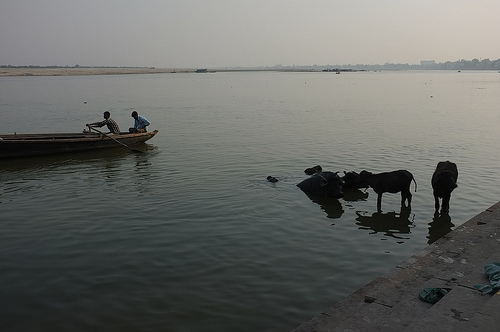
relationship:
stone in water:
[268, 174, 280, 183] [4, 1, 500, 323]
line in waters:
[3, 55, 500, 74] [5, 58, 500, 325]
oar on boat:
[89, 126, 137, 155] [1, 117, 162, 162]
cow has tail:
[354, 164, 416, 221] [415, 176, 421, 195]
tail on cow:
[415, 176, 421, 195] [354, 164, 416, 221]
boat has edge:
[1, 117, 162, 162] [2, 130, 160, 146]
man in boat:
[83, 110, 125, 139] [1, 117, 162, 162]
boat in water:
[1, 117, 162, 162] [4, 1, 500, 323]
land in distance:
[1, 66, 204, 79] [3, 0, 495, 133]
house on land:
[195, 67, 211, 71] [1, 66, 204, 79]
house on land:
[71, 62, 82, 72] [1, 66, 204, 79]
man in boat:
[128, 109, 153, 135] [1, 117, 162, 162]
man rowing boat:
[83, 110, 125, 139] [1, 117, 162, 162]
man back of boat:
[128, 109, 153, 135] [1, 117, 162, 162]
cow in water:
[354, 164, 416, 221] [4, 1, 500, 323]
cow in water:
[429, 158, 460, 218] [4, 1, 500, 323]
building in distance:
[324, 67, 356, 72] [3, 0, 495, 133]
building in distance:
[419, 59, 439, 63] [3, 0, 495, 133]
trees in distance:
[260, 55, 500, 72] [3, 0, 495, 133]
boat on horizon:
[1, 117, 162, 162] [3, 0, 495, 133]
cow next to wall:
[354, 164, 416, 221] [291, 198, 500, 330]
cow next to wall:
[429, 158, 460, 218] [291, 198, 500, 330]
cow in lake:
[354, 164, 416, 221] [5, 65, 500, 321]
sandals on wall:
[421, 280, 456, 303] [291, 198, 500, 330]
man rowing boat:
[128, 109, 153, 135] [1, 117, 162, 162]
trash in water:
[299, 161, 363, 201] [4, 1, 500, 323]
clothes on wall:
[472, 257, 500, 303] [291, 198, 500, 330]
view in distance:
[5, 40, 499, 97] [3, 0, 495, 133]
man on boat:
[83, 110, 125, 139] [1, 117, 162, 162]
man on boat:
[128, 109, 153, 135] [1, 117, 162, 162]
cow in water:
[295, 168, 346, 203] [4, 1, 500, 323]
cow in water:
[341, 166, 369, 192] [4, 1, 500, 323]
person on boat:
[128, 109, 153, 135] [1, 117, 162, 162]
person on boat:
[83, 110, 125, 139] [1, 117, 162, 162]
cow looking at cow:
[354, 164, 416, 221] [295, 168, 346, 203]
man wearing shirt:
[128, 109, 153, 135] [131, 117, 152, 131]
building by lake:
[324, 67, 356, 72] [5, 65, 500, 321]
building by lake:
[419, 59, 439, 63] [5, 65, 500, 321]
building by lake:
[195, 66, 212, 77] [5, 65, 500, 321]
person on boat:
[88, 108, 122, 138] [1, 117, 162, 162]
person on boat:
[127, 103, 156, 132] [1, 117, 162, 162]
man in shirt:
[128, 109, 153, 135] [131, 117, 152, 131]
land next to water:
[1, 66, 204, 79] [4, 1, 500, 323]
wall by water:
[291, 198, 500, 330] [4, 1, 500, 323]